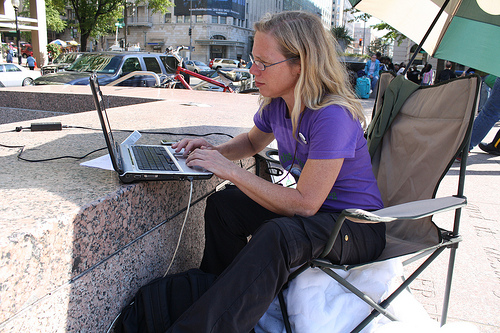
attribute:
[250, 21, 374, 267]
woman — typing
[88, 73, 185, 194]
laptop — black, open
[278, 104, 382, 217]
shirt — periwinkle blue, purple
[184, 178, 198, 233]
cord — white, hanging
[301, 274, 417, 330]
blanket — white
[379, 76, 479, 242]
chair — tan, brown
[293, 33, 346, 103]
hair — blond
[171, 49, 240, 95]
bicycle — red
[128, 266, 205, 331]
backpack — black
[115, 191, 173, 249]
wall — stone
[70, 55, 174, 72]
vehicle — blue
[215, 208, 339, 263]
pants — black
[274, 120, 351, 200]
arms — peach colored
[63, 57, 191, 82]
suv — parked, blue